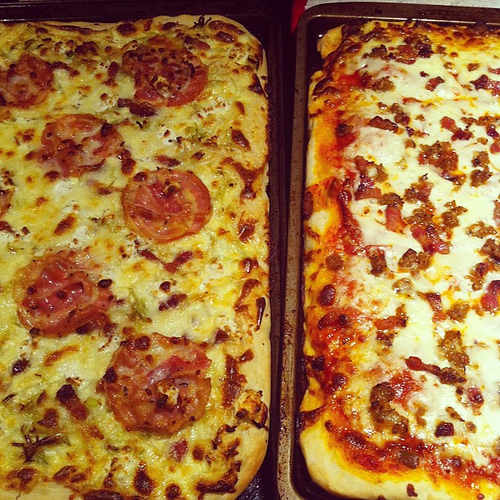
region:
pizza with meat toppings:
[3, 30, 111, 177]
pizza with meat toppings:
[98, 45, 239, 236]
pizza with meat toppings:
[13, 152, 198, 317]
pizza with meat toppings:
[128, 179, 245, 367]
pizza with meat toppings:
[9, 216, 111, 463]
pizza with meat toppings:
[96, 245, 243, 469]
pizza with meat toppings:
[326, 41, 416, 201]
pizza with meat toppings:
[416, 53, 489, 260]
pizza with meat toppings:
[325, 213, 415, 467]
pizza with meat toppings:
[391, 214, 485, 454]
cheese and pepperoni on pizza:
[0, 20, 215, 129]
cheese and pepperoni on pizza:
[108, 39, 258, 224]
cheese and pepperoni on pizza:
[14, 195, 156, 402]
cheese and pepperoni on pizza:
[3, 362, 236, 477]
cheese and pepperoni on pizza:
[130, 160, 258, 381]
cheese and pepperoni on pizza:
[10, 97, 143, 284]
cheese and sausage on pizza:
[327, 30, 439, 175]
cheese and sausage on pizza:
[327, 126, 474, 276]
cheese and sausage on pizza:
[315, 212, 479, 377]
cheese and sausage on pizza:
[304, 301, 491, 480]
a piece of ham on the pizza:
[119, 163, 214, 245]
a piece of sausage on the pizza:
[353, 177, 383, 204]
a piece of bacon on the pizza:
[388, 366, 421, 405]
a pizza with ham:
[1, 9, 274, 499]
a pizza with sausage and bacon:
[296, 16, 499, 497]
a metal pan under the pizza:
[276, 0, 498, 499]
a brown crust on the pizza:
[295, 425, 452, 498]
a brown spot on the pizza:
[228, 120, 254, 155]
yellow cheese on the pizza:
[19, 183, 64, 228]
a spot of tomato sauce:
[330, 127, 362, 148]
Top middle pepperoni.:
[115, 36, 210, 108]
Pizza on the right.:
[289, 12, 499, 497]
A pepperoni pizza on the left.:
[0, 15, 275, 498]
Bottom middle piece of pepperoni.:
[102, 332, 216, 435]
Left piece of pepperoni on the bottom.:
[12, 256, 113, 339]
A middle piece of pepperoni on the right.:
[121, 168, 213, 243]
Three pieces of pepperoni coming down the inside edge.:
[102, 33, 214, 436]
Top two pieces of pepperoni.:
[0, 40, 210, 110]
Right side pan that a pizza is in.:
[277, 4, 498, 497]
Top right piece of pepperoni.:
[111, 30, 210, 111]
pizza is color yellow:
[42, 165, 326, 486]